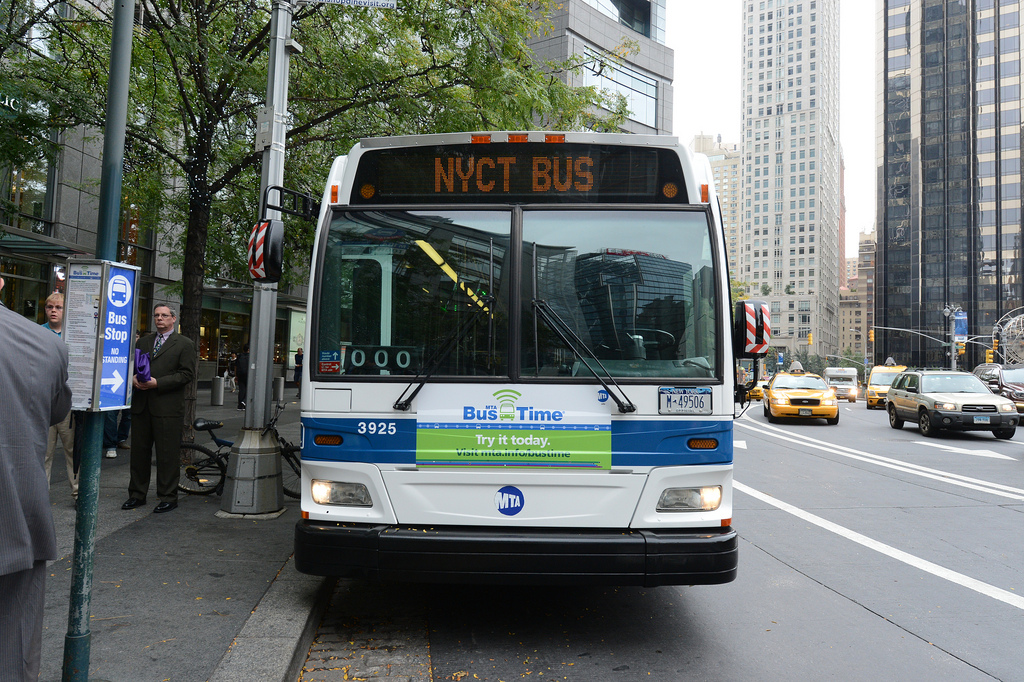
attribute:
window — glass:
[756, 221, 769, 237]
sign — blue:
[105, 258, 140, 407]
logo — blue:
[495, 482, 524, 514]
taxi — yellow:
[760, 369, 841, 424]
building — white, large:
[734, 5, 848, 341]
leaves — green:
[348, 64, 440, 153]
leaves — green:
[422, 33, 533, 120]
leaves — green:
[187, 42, 219, 87]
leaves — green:
[138, 59, 167, 91]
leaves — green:
[612, 30, 642, 60]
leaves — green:
[604, 91, 636, 127]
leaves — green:
[497, 2, 545, 40]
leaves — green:
[431, 69, 486, 118]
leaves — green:
[492, 68, 560, 119]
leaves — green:
[214, 122, 254, 164]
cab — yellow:
[759, 356, 845, 432]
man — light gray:
[0, 267, 73, 675]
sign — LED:
[355, 133, 682, 209]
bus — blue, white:
[303, 122, 747, 607]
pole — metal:
[210, 259, 293, 528]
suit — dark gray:
[127, 325, 199, 509]